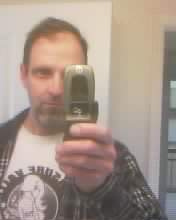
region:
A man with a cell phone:
[3, 5, 154, 219]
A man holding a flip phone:
[3, 4, 150, 217]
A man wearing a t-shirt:
[4, 9, 175, 218]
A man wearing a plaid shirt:
[0, 9, 153, 218]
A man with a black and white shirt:
[2, 8, 156, 218]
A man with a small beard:
[1, 8, 93, 138]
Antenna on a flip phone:
[90, 93, 102, 126]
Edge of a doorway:
[152, 18, 174, 218]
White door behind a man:
[1, 3, 118, 168]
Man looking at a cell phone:
[3, 5, 147, 218]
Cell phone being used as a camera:
[58, 58, 97, 126]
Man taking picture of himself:
[12, 24, 102, 129]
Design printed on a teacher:
[0, 154, 61, 215]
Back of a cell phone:
[60, 58, 98, 122]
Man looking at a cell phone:
[18, 19, 93, 125]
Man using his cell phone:
[12, 14, 111, 146]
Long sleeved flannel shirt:
[1, 101, 166, 218]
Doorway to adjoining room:
[150, 10, 175, 206]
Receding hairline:
[19, 12, 91, 65]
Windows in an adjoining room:
[165, 72, 174, 147]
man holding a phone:
[15, 15, 129, 166]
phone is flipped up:
[58, 67, 107, 143]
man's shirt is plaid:
[1, 110, 164, 217]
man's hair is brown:
[15, 6, 92, 68]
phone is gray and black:
[56, 58, 107, 133]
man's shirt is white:
[6, 120, 70, 217]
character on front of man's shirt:
[0, 155, 49, 218]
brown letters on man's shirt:
[1, 154, 79, 211]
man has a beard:
[33, 92, 74, 132]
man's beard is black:
[35, 102, 74, 132]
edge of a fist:
[101, 151, 109, 169]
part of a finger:
[67, 165, 87, 188]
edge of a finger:
[59, 164, 73, 180]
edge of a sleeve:
[95, 182, 107, 191]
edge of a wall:
[154, 170, 163, 185]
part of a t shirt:
[35, 155, 46, 164]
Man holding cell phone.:
[16, 16, 130, 180]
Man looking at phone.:
[14, 21, 125, 185]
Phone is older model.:
[7, 18, 125, 172]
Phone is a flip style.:
[16, 12, 124, 180]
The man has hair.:
[15, 14, 106, 142]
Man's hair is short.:
[13, 12, 108, 140]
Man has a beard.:
[11, 16, 110, 135]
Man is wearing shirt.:
[1, 15, 168, 219]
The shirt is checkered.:
[0, 104, 167, 219]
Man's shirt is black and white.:
[0, 104, 169, 218]